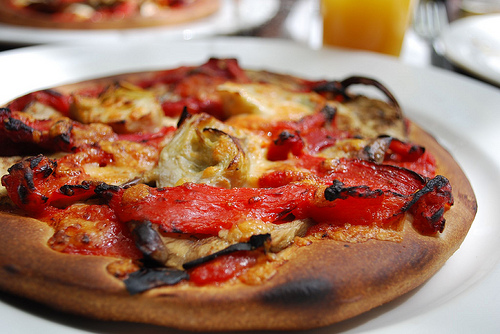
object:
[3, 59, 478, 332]
pizza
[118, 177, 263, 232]
pepperoni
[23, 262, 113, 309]
crust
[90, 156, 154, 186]
cheese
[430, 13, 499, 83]
plate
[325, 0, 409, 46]
juice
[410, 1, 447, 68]
fork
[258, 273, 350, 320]
crust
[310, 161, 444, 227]
pepper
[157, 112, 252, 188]
artichoke